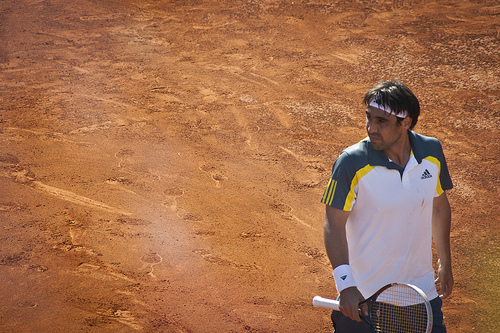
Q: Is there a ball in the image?
A: No, there are no balls.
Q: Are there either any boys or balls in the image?
A: No, there are no balls or boys.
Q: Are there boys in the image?
A: No, there are no boys.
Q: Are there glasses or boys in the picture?
A: No, there are no boys or glasses.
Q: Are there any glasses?
A: No, there are no glasses.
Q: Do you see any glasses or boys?
A: No, there are no glasses or boys.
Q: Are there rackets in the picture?
A: Yes, there is a racket.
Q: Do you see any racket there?
A: Yes, there is a racket.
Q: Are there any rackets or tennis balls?
A: Yes, there is a racket.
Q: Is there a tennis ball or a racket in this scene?
A: Yes, there is a racket.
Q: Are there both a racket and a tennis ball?
A: No, there is a racket but no tennis balls.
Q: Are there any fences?
A: No, there are no fences.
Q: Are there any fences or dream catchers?
A: No, there are no fences or dream catchers.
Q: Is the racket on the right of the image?
A: Yes, the racket is on the right of the image.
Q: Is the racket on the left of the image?
A: No, the racket is on the right of the image.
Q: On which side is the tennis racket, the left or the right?
A: The tennis racket is on the right of the image.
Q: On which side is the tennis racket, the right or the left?
A: The tennis racket is on the right of the image.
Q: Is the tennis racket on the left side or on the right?
A: The tennis racket is on the right of the image.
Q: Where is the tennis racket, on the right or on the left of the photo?
A: The tennis racket is on the right of the image.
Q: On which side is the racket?
A: The racket is on the right of the image.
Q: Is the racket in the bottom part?
A: Yes, the racket is in the bottom of the image.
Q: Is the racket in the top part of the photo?
A: No, the racket is in the bottom of the image.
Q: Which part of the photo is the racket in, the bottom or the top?
A: The racket is in the bottom of the image.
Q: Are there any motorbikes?
A: No, there are no motorbikes.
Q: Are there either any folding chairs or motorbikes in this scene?
A: No, there are no motorbikes or folding chairs.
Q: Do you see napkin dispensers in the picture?
A: No, there are no napkin dispensers.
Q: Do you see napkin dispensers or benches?
A: No, there are no napkin dispensers or benches.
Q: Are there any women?
A: No, there are no women.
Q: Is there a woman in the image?
A: No, there are no women.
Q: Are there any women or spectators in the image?
A: No, there are no women or spectators.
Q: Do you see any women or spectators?
A: No, there are no women or spectators.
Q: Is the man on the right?
A: Yes, the man is on the right of the image.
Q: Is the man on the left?
A: No, the man is on the right of the image.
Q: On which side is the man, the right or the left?
A: The man is on the right of the image.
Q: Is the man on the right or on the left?
A: The man is on the right of the image.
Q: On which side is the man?
A: The man is on the right of the image.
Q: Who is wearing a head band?
A: The man is wearing a head band.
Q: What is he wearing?
A: The man is wearing a hair band.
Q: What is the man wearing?
A: The man is wearing a hair band.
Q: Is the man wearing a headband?
A: Yes, the man is wearing a headband.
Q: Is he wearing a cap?
A: No, the man is wearing a headband.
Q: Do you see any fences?
A: No, there are no fences.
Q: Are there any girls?
A: No, there are no girls.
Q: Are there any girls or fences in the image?
A: No, there are no girls or fences.